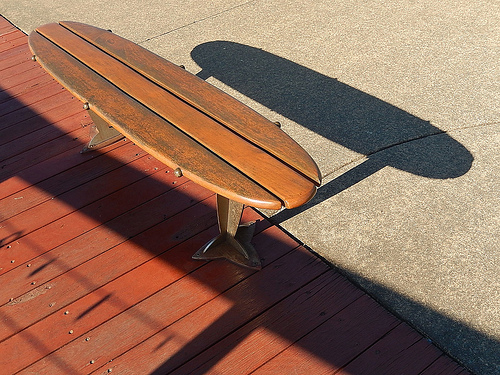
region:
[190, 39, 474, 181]
A black shadow on the ground of a bench.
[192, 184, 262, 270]
A brown bench leg that mostly visible.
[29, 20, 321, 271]
A long surfboard bench.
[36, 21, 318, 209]
Middle orange colored slat on a bench.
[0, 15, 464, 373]
Red wooden walkway.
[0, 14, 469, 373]
Red wood boards making up a walkway.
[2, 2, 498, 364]
A concrete walkway with shadows on it.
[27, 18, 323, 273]
A wood bench resembling a surfboard.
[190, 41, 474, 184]
Shadow of a surfboard bench.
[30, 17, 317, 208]
Oblong wooden bench on boards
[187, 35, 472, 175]
Shadow of bench on boards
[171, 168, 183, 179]
Wooden peg in a bench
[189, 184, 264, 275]
Metal leg on a bench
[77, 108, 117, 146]
Metal leg on a bench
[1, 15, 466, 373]
Sidewalk made from wooden slats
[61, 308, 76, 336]
Holes for screws in board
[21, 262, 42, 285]
Holes for screws in board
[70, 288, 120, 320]
Shadow on a wooden board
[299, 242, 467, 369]
Crack between boards and concrete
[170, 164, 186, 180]
the screws are bronze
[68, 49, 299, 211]
the screws on board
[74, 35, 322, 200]
the surfboard is wooden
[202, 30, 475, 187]
shadow on the ground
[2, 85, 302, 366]
the deck is wooden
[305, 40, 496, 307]
the ground is concrete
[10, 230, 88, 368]
holes in the deck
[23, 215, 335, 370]
shadows on the deck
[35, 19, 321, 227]
slats on the bench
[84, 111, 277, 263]
legs on the bench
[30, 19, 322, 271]
Orange colored wooden surfboard bench.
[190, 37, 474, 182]
Dark shadow of a bench on the ground.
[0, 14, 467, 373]
A red wood walkway.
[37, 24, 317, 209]
Middle orange slat on the wood surfboard bench.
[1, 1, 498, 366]
Concrete walkway with a shadow on it.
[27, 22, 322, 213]
The top of a three slat surfboard bench.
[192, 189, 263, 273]
A brown mostly visible bench leg.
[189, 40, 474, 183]
Shadow of the bench on the concrete.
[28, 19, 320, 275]
A word wooden surfboard bench.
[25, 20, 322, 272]
A wooden bench that resembles a surfboard.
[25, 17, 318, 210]
Oblong wooden bench on a boardwalk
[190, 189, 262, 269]
Metal leg of bench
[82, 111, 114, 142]
Metal leg of bench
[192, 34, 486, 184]
Shadow of bench on concrete